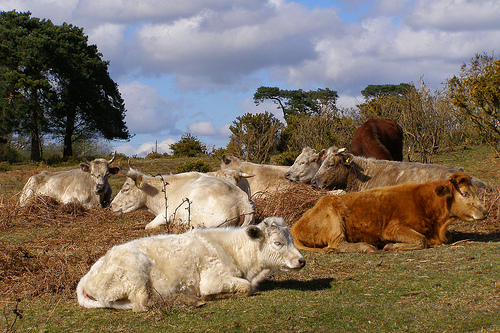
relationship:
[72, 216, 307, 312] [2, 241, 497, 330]
cow laying on ground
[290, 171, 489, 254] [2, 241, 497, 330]
cow laying on ground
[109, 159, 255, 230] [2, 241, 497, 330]
cow laying on ground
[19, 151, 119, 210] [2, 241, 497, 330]
cow laying on ground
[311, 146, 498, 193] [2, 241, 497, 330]
cow laying on ground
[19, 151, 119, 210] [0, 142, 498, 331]
cow laying on ground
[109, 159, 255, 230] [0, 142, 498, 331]
cow laying on ground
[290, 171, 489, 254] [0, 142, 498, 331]
cow laying on ground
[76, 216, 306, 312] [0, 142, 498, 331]
cow laying on ground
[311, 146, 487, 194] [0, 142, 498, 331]
cow laying on ground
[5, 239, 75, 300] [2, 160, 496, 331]
hay on ground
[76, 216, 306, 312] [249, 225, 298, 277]
cow has head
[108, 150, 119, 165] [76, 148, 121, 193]
horn on head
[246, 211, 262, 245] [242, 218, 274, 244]
tag in ear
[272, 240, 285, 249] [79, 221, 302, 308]
eye of a cow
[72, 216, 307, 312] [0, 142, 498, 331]
cow laying on ground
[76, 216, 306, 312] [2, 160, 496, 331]
cow laying on ground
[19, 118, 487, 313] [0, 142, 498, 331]
cows laying on ground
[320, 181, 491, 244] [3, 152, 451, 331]
cow laying on ground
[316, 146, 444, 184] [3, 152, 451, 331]
cow laying on ground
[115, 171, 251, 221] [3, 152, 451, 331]
cow laying on ground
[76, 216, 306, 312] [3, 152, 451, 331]
cow laying on ground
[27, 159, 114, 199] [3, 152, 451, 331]
cow laying on ground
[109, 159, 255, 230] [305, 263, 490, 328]
cow laying on ground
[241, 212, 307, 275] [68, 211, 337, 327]
head of a cow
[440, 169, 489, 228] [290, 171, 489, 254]
head of a cow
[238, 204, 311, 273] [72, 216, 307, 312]
head of a cow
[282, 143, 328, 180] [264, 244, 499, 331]
cow lying in grass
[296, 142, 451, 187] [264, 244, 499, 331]
cow lying in grass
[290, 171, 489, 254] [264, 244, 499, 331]
cow lying in grass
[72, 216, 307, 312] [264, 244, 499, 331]
cow lying in grass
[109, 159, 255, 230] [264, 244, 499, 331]
cow lying in grass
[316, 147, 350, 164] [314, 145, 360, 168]
tags on ears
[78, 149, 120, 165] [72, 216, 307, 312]
horns of cow